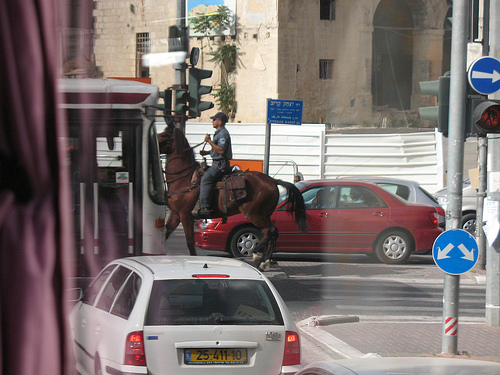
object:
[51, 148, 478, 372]
traffic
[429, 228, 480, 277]
sign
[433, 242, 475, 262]
arrows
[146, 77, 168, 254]
front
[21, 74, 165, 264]
bus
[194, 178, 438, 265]
car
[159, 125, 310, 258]
horse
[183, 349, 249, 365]
license plate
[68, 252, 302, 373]
car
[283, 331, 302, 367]
light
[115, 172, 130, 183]
sticker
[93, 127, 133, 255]
window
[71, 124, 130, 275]
door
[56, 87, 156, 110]
stripe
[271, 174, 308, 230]
tail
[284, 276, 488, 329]
road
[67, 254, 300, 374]
station wagon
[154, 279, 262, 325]
window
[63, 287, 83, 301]
mirror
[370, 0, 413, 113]
opening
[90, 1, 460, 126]
building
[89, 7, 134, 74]
wall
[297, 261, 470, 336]
street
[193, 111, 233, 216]
officer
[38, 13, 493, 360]
intersection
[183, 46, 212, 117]
signal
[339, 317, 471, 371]
sidewalk